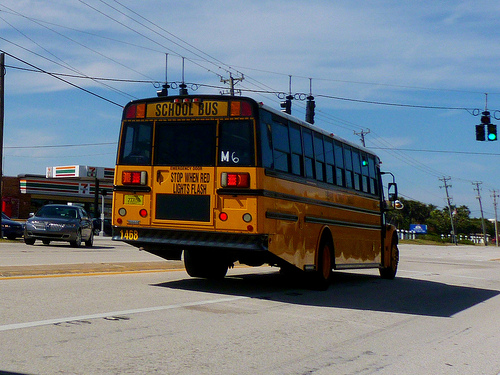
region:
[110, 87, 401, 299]
Yellow school bus in street.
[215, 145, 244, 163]
'M6' written in white on bus.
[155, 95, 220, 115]
'School Bus' written in black on back of bus.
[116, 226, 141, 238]
'1468' written in yellow on back of bus.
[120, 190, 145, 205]
Yellow license plate on back of bus.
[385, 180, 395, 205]
Black side rear view mirror.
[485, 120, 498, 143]
Black traffic signal showing green light.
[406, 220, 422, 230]
Blue and white sign on side of road.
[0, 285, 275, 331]
Painted white line in the street.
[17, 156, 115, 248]
7-11 store on side of the road.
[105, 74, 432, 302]
yellow school bus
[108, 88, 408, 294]
bus on the road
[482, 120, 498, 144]
traffic light shining green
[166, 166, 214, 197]
black writing on the back of the bus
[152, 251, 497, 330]
shadow from the bus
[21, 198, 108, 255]
car on the road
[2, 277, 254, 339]
white line on the road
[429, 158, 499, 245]
powerlines on the side of the road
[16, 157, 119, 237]
seven eleven building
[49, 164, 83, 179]
red, green, and orange stripes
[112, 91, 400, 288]
Yellow school bus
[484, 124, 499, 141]
Traffic signal lit green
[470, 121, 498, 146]
Two traffic signals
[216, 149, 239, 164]
M6 written in white on the back of a school bus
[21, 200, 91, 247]
Gray car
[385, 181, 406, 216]
Rear view mirror on school bus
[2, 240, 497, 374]
Multiple lane road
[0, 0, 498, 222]
Cloudy blue sky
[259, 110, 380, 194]
Row of windows on the side of a bus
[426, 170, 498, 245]
Three power line supports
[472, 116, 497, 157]
green light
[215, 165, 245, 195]
rear tail light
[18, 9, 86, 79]
white clouds in blue sky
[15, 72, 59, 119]
white clouds in blue sky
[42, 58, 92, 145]
white clouds in blue sky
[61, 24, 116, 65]
white clouds in blue sky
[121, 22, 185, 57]
white clouds in blue sky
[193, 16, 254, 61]
white clouds in blue sky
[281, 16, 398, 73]
white clouds in blue sky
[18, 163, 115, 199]
sign advertising a 7-Eleven store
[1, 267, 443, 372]
white lane line in road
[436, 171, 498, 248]
three utility poles in a row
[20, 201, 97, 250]
vehicle pulling onto the street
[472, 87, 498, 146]
suspended traffic light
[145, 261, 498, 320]
shadow of bus on the road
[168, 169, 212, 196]
warning to stop when red lights flash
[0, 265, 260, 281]
painted yellow lane marker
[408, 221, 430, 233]
blue advertisement billboard